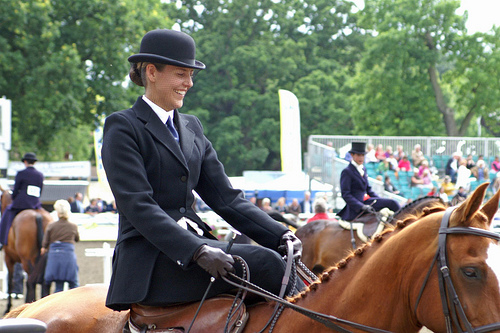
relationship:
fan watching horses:
[298, 188, 312, 214] [324, 178, 498, 331]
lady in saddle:
[66, 27, 311, 308] [129, 300, 230, 332]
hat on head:
[129, 28, 210, 74] [135, 63, 198, 101]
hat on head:
[348, 141, 375, 164] [346, 151, 372, 164]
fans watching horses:
[398, 144, 498, 199] [324, 178, 498, 331]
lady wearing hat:
[66, 27, 311, 308] [129, 28, 210, 74]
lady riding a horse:
[66, 27, 393, 299] [16, 194, 500, 330]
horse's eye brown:
[453, 255, 485, 286] [476, 258, 492, 280]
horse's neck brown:
[360, 284, 416, 332] [405, 299, 419, 320]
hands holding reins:
[192, 230, 339, 283] [246, 256, 333, 332]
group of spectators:
[59, 132, 497, 206] [245, 173, 338, 222]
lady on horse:
[66, 27, 311, 308] [16, 194, 500, 330]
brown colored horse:
[405, 299, 419, 320] [16, 194, 500, 330]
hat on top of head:
[129, 28, 210, 74] [135, 63, 198, 101]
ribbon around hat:
[178, 57, 199, 66] [129, 28, 210, 74]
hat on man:
[348, 141, 375, 164] [333, 145, 379, 220]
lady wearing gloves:
[66, 27, 393, 299] [199, 243, 231, 278]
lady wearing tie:
[66, 27, 311, 308] [165, 119, 186, 154]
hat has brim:
[129, 28, 210, 74] [136, 57, 210, 69]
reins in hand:
[246, 256, 333, 332] [272, 225, 311, 279]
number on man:
[19, 177, 53, 209] [16, 123, 54, 250]